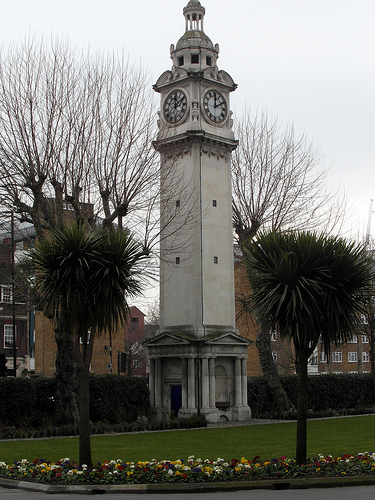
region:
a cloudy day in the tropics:
[5, 7, 371, 377]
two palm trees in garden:
[32, 204, 367, 377]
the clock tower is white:
[123, 14, 289, 449]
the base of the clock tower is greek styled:
[145, 293, 278, 432]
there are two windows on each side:
[151, 178, 290, 307]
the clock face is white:
[124, 58, 249, 165]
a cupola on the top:
[157, 10, 302, 139]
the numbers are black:
[133, 75, 242, 174]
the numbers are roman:
[150, 62, 265, 145]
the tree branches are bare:
[37, 65, 194, 211]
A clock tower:
[136, 7, 258, 222]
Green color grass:
[147, 438, 256, 453]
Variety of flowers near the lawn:
[18, 451, 267, 485]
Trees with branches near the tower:
[24, 141, 328, 429]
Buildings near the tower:
[8, 226, 133, 361]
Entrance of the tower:
[164, 377, 186, 422]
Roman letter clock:
[203, 89, 237, 118]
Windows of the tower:
[208, 195, 225, 272]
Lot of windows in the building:
[334, 333, 372, 364]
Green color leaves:
[268, 247, 345, 324]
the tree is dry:
[17, 56, 142, 195]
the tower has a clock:
[203, 89, 231, 122]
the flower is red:
[119, 466, 125, 470]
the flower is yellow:
[241, 456, 249, 464]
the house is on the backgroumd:
[1, 171, 148, 333]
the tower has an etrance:
[160, 382, 189, 417]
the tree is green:
[255, 232, 351, 344]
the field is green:
[103, 418, 373, 458]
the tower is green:
[150, 156, 236, 334]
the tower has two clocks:
[158, 2, 228, 337]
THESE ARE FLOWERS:
[0, 448, 373, 492]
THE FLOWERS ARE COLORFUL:
[0, 445, 373, 485]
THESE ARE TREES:
[23, 206, 374, 476]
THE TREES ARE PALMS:
[16, 211, 373, 472]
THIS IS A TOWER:
[140, 0, 253, 436]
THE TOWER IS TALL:
[145, 0, 253, 428]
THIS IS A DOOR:
[163, 373, 186, 421]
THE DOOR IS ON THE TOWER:
[162, 373, 190, 423]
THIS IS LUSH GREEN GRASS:
[1, 406, 374, 467]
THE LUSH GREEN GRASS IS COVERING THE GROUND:
[0, 408, 374, 471]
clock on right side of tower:
[202, 89, 236, 128]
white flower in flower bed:
[178, 463, 188, 471]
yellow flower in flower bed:
[239, 455, 250, 464]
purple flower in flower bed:
[119, 459, 129, 465]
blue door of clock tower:
[173, 372, 187, 422]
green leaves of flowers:
[80, 475, 128, 487]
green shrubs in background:
[105, 385, 138, 411]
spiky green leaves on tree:
[288, 308, 348, 342]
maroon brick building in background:
[98, 347, 121, 368]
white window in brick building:
[349, 352, 361, 371]